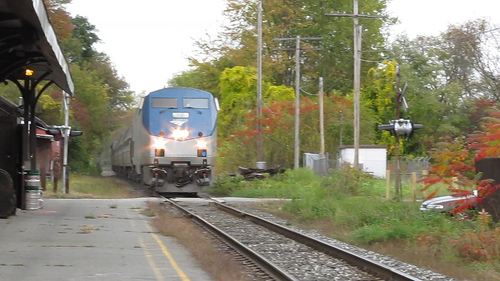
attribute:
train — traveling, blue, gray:
[97, 83, 228, 193]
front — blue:
[152, 83, 219, 191]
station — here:
[9, 3, 83, 218]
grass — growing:
[260, 178, 451, 237]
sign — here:
[381, 79, 414, 121]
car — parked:
[415, 191, 478, 215]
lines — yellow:
[120, 199, 195, 280]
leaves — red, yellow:
[272, 89, 300, 122]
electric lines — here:
[279, 31, 378, 93]